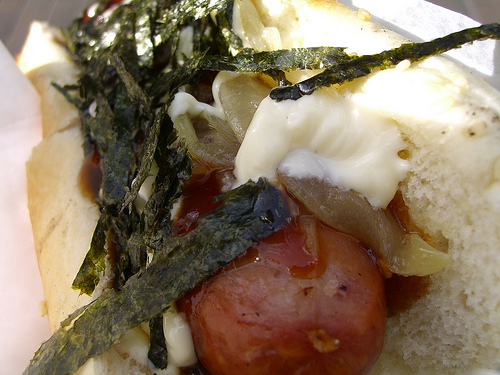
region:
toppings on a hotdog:
[88, 0, 393, 370]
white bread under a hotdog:
[22, 41, 177, 366]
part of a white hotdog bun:
[271, 0, 496, 361]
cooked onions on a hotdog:
[177, 71, 442, 268]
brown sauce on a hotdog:
[88, 131, 218, 219]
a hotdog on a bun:
[33, 101, 485, 372]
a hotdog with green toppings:
[87, 38, 397, 373]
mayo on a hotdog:
[248, 90, 403, 209]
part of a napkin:
[353, 0, 496, 92]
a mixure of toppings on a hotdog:
[85, 56, 402, 370]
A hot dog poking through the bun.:
[191, 231, 394, 373]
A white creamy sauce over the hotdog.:
[228, 90, 417, 212]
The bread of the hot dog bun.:
[24, 141, 89, 296]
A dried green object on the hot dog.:
[91, 89, 163, 266]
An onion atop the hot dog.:
[214, 78, 261, 134]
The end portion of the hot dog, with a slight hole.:
[305, 318, 341, 363]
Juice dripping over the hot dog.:
[276, 228, 318, 283]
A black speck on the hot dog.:
[336, 278, 350, 295]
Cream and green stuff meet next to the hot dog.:
[143, 315, 190, 367]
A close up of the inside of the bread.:
[431, 305, 490, 360]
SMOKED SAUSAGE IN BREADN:
[115, 172, 451, 372]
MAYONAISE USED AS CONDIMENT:
[220, 75, 420, 205]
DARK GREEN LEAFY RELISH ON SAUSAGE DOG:
[35, 5, 290, 285]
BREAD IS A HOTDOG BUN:
[56, 12, 471, 352]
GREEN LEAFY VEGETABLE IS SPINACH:
[31, 1, 366, 248]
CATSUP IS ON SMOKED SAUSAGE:
[125, 160, 456, 342]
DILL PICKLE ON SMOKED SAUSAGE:
[142, 64, 463, 283]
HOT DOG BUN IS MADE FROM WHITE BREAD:
[336, 79, 496, 356]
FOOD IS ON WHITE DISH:
[357, 5, 498, 98]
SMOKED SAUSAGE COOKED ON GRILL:
[163, 167, 426, 370]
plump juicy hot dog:
[151, 137, 391, 370]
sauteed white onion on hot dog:
[275, 165, 448, 283]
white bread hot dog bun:
[16, 12, 498, 364]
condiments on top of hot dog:
[61, 4, 433, 354]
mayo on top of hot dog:
[247, 80, 418, 213]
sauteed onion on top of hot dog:
[181, 56, 271, 161]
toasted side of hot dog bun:
[19, 14, 192, 372]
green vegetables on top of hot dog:
[61, 11, 254, 314]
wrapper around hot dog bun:
[3, 30, 68, 373]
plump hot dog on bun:
[123, 153, 401, 372]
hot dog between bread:
[132, 94, 388, 367]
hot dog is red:
[139, 150, 393, 372]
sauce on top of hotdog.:
[148, 150, 328, 289]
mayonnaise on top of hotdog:
[230, 74, 406, 213]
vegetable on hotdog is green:
[33, 3, 454, 373]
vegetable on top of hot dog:
[12, 0, 498, 371]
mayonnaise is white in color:
[241, 53, 471, 205]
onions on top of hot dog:
[166, 65, 444, 282]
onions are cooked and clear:
[165, 62, 444, 282]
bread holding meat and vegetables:
[13, 1, 498, 373]